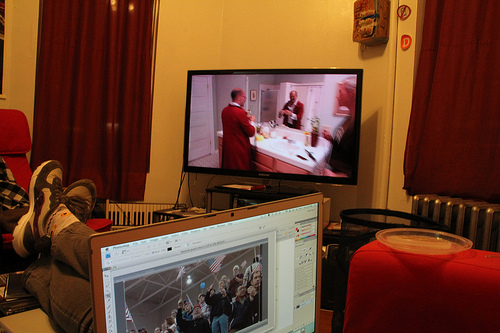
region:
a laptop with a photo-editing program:
[82, 190, 340, 331]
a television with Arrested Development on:
[181, 62, 359, 184]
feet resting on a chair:
[3, 144, 108, 258]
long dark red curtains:
[33, 1, 153, 209]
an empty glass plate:
[373, 215, 440, 268]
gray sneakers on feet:
[11, 155, 101, 255]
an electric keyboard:
[85, 194, 197, 233]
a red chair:
[0, 90, 117, 257]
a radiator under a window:
[403, 152, 497, 257]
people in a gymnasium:
[123, 238, 271, 330]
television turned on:
[176, 49, 369, 189]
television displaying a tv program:
[169, 56, 364, 190]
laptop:
[67, 184, 331, 331]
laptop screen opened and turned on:
[70, 193, 354, 330]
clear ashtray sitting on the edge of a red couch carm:
[375, 214, 473, 263]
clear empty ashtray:
[374, 213, 471, 259]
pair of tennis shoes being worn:
[10, 151, 92, 253]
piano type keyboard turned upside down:
[105, 189, 184, 226]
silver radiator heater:
[408, 172, 496, 254]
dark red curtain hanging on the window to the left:
[33, 0, 147, 210]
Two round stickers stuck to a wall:
[391, 1, 412, 52]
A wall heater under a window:
[400, 186, 498, 247]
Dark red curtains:
[20, 1, 171, 236]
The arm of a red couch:
[353, 232, 495, 326]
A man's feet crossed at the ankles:
[13, 175, 113, 325]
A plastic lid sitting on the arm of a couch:
[365, 218, 483, 260]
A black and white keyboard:
[101, 187, 196, 227]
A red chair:
[5, 103, 111, 249]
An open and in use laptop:
[77, 207, 358, 324]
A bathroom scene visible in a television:
[171, 57, 378, 194]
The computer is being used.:
[70, 186, 347, 327]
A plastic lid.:
[365, 206, 477, 271]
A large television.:
[170, 55, 365, 190]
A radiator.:
[405, 190, 495, 267]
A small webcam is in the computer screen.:
[212, 195, 252, 231]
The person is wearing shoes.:
[0, 160, 125, 296]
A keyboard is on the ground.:
[87, 195, 188, 230]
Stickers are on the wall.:
[390, 0, 420, 52]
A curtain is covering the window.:
[25, 0, 165, 200]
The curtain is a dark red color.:
[30, 0, 168, 201]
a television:
[180, 67, 365, 187]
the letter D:
[398, 32, 413, 54]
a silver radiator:
[407, 190, 497, 250]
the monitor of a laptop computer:
[85, 187, 325, 329]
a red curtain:
[30, 0, 156, 155]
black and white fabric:
[0, 152, 25, 207]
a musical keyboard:
[103, 196, 178, 227]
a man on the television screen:
[220, 85, 256, 166]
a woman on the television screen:
[316, 72, 354, 174]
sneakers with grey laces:
[10, 157, 97, 259]